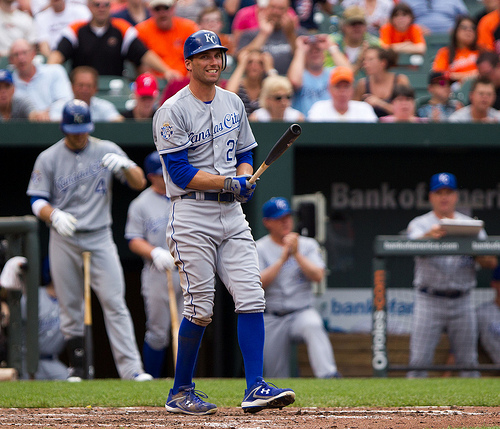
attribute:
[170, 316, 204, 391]
sock — blue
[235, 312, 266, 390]
sock — blue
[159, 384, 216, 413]
sneaker — blue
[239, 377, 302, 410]
sneaker — blue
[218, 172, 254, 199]
glove — blue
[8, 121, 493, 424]
game — baseball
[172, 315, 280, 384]
socks — blue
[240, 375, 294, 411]
cleat — blue, white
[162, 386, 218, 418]
cleat — blue, white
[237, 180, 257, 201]
gloves — blue, gray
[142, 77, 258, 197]
jersey — gray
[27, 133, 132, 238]
jersey — gray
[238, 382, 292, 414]
shoe — blue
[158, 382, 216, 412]
shoe — blue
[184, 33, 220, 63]
baseball cap — blue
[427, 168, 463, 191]
baseball cap — blue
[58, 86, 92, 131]
baseball cap — blue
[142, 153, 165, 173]
baseball cap — blue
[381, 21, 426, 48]
shirt — orange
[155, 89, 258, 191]
long sleeve shirt — long sleeved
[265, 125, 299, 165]
bat is black — yellow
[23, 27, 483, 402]
people are playing — baseball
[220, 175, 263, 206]
grey gloves — gray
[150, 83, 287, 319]
grey uniform — gray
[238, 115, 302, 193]
player with bat — leaning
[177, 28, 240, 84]
player's head — a blue helmet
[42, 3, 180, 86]
man — in the background